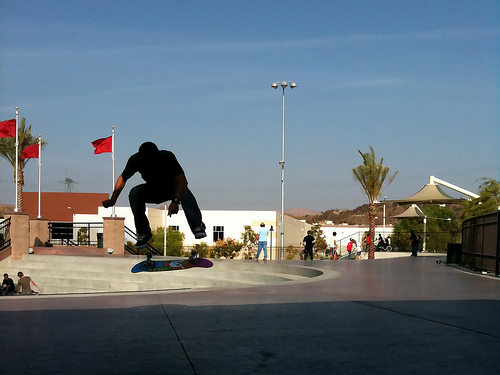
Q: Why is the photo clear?
A: Its during the day.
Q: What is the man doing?
A: Skating.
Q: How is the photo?
A: Clear.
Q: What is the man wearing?
A: Clothes.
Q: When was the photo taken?
A: Daytime.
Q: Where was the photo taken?
A: At a park.